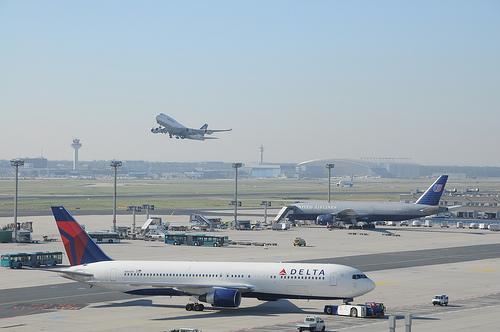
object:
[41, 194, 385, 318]
airplane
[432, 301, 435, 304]
pole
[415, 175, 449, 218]
tail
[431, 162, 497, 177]
mountains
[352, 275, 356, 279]
window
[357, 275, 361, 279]
window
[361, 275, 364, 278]
window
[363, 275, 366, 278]
window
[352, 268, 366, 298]
cockpit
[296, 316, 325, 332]
vehicle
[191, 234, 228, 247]
vehicle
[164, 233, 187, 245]
vehicle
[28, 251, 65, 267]
vehicle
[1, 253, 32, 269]
vehicle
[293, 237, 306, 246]
vehicle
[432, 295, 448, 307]
vehicle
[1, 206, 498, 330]
airport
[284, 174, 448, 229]
airplane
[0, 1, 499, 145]
sky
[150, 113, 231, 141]
airplane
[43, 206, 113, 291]
tail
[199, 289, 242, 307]
engine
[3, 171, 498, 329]
airport